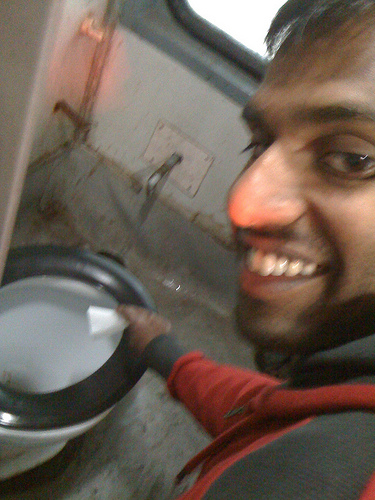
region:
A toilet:
[2, 233, 169, 458]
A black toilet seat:
[2, 241, 165, 455]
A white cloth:
[77, 295, 184, 348]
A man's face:
[220, 2, 373, 360]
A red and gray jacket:
[126, 325, 374, 498]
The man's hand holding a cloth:
[80, 304, 186, 357]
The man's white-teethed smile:
[214, 229, 327, 295]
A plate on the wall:
[126, 109, 217, 199]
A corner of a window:
[160, 0, 325, 90]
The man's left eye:
[303, 122, 372, 197]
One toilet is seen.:
[15, 250, 146, 419]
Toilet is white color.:
[4, 412, 57, 467]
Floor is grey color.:
[120, 430, 161, 490]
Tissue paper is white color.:
[92, 302, 137, 334]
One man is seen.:
[214, 171, 330, 460]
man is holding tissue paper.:
[85, 293, 205, 377]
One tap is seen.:
[135, 140, 186, 219]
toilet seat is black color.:
[35, 376, 104, 426]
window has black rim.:
[173, 5, 266, 88]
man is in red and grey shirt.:
[222, 408, 344, 486]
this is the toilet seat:
[14, 252, 86, 277]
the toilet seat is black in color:
[15, 399, 56, 420]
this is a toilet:
[9, 257, 63, 467]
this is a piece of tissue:
[88, 308, 115, 333]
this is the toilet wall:
[113, 62, 152, 130]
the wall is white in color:
[140, 225, 203, 256]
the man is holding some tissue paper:
[114, 303, 169, 350]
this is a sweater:
[200, 361, 241, 400]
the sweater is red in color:
[187, 368, 231, 396]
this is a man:
[217, 48, 371, 484]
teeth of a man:
[233, 251, 296, 276]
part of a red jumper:
[204, 388, 247, 418]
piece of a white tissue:
[98, 299, 128, 335]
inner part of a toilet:
[18, 315, 68, 356]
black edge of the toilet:
[41, 249, 111, 267]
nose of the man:
[226, 183, 291, 225]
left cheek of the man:
[331, 208, 361, 253]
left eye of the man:
[324, 139, 369, 174]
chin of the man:
[229, 316, 286, 352]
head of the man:
[270, 26, 360, 96]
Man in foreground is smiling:
[203, 2, 373, 363]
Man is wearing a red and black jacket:
[143, 325, 374, 498]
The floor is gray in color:
[0, 171, 241, 492]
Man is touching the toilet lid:
[30, 242, 202, 435]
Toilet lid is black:
[15, 240, 181, 426]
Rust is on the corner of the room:
[40, 34, 142, 202]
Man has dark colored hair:
[260, 3, 374, 66]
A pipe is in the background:
[127, 143, 190, 213]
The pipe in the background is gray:
[112, 144, 190, 211]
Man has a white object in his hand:
[84, 298, 145, 338]